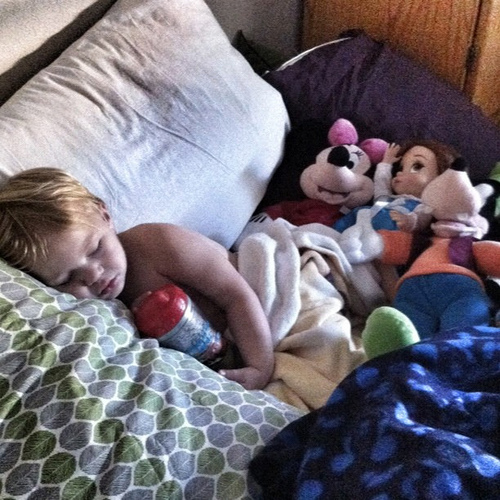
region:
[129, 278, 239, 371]
This is a bottle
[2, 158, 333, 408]
This is a child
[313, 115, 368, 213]
This is a doll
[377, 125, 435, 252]
This is a doll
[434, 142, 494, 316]
This is a doll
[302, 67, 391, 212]
This is a doll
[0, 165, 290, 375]
a little boy a sleep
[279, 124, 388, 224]
a Minne mouse doll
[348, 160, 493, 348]
a goofy stuffed animal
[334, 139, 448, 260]
a princess doll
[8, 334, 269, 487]
a polka dotted pillow case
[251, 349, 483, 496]
a blue and black blanket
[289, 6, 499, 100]
a wooden cabinet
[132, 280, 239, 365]
a cup with a red lid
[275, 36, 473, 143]
a purple pillow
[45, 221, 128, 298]
a face of a child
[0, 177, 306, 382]
a kid sleeping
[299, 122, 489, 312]
three different disney characters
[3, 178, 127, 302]
the head of the kid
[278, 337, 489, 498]
a dark blue bed sheet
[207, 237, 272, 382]
one arm of the kid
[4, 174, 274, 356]
a blond kid resting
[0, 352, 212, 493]
a bed sheet with different leaves design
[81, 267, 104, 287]
the nose of the kid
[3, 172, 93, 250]
the child's blond hair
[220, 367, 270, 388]
one hand of the child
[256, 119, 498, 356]
stuffed disney characters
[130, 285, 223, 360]
a red sippie cup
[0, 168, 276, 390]
a small blonde child sleeping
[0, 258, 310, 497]
leaf patterned pillow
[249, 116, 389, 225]
a stuffed minnie mouse toy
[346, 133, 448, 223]
a stuffed Belle doll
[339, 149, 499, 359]
a stuffed Goofy character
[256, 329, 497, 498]
a dark and light blue blanket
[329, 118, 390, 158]
a pink bow in a toy's hair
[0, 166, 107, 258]
blonde hair on a toddler's head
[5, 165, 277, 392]
a toddler sleeping on the couch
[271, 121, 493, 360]
the disney toys laying next to the child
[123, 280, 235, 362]
the cup the child was holding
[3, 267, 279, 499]
the pillow the child is laying on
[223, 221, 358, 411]
the pink blanket covering up the kid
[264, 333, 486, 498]
a dark blue blanket in the corner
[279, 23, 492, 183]
another pillow sitting next to the wall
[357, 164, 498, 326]
a stuffed animal that looks like Goofy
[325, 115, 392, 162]
the bow on the Minnie Mouse doll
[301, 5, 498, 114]
a wooden cabinet next to the pillow